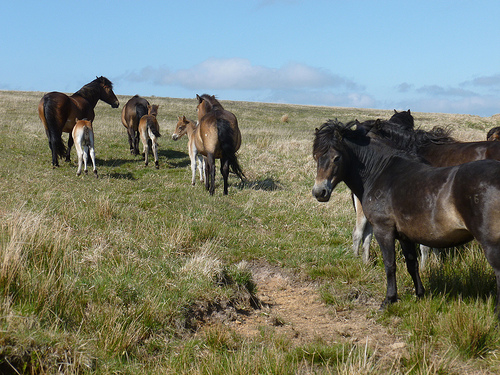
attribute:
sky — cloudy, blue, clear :
[0, 2, 496, 117]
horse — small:
[71, 115, 98, 178]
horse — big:
[39, 62, 110, 163]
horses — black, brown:
[267, 103, 492, 291]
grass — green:
[60, 175, 94, 201]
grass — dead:
[4, 215, 35, 238]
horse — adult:
[35, 75, 120, 167]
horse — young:
[69, 115, 97, 175]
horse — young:
[120, 93, 150, 152]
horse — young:
[137, 103, 161, 166]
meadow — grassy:
[1, 91, 496, 373]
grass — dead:
[21, 126, 284, 349]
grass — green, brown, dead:
[8, 86, 497, 373]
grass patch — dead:
[204, 246, 473, 373]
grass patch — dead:
[179, 235, 429, 373]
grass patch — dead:
[235, 128, 344, 209]